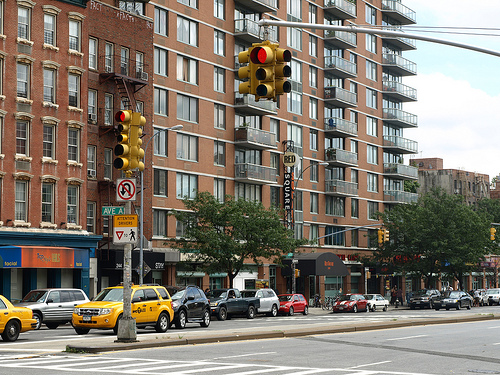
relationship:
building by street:
[0, 0, 418, 310] [3, 307, 500, 375]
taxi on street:
[74, 281, 175, 333] [3, 307, 500, 375]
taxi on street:
[0, 295, 38, 342] [3, 307, 500, 375]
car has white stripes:
[332, 292, 371, 313] [340, 300, 347, 306]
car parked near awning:
[332, 292, 371, 313] [283, 251, 347, 276]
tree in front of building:
[168, 189, 319, 291] [0, 0, 418, 310]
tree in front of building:
[362, 180, 500, 289] [0, 0, 418, 310]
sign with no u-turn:
[116, 178, 138, 202] [120, 183, 133, 196]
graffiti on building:
[88, 0, 154, 32] [0, 0, 418, 310]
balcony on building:
[324, 179, 359, 200] [0, 0, 418, 310]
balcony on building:
[326, 147, 359, 168] [0, 0, 418, 310]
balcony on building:
[324, 115, 358, 136] [0, 0, 418, 310]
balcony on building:
[323, 84, 357, 109] [0, 0, 418, 310]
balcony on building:
[321, 54, 360, 81] [0, 0, 418, 310]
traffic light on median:
[112, 107, 146, 176] [66, 312, 499, 355]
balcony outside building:
[324, 179, 359, 200] [0, 0, 418, 310]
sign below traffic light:
[116, 178, 138, 202] [112, 107, 146, 176]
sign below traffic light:
[113, 215, 140, 245] [112, 107, 146, 176]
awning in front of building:
[283, 251, 347, 276] [0, 0, 418, 310]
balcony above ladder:
[100, 54, 150, 90] [114, 76, 138, 112]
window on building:
[174, 130, 200, 163] [0, 0, 418, 310]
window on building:
[177, 91, 201, 124] [0, 0, 418, 310]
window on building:
[177, 53, 198, 86] [0, 0, 418, 310]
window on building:
[177, 171, 199, 202] [0, 0, 418, 310]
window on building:
[177, 13, 201, 49] [0, 0, 418, 310]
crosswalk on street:
[1, 346, 434, 374] [3, 307, 500, 375]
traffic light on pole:
[112, 107, 146, 176] [118, 174, 138, 341]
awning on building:
[283, 251, 347, 276] [0, 0, 418, 310]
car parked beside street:
[277, 292, 311, 315] [3, 307, 500, 375]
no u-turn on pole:
[120, 183, 133, 196] [118, 174, 138, 341]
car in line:
[277, 292, 311, 315] [201, 288, 310, 315]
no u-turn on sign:
[120, 183, 133, 196] [116, 178, 138, 202]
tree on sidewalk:
[168, 189, 319, 291] [307, 305, 332, 315]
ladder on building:
[114, 76, 138, 112] [0, 0, 418, 310]